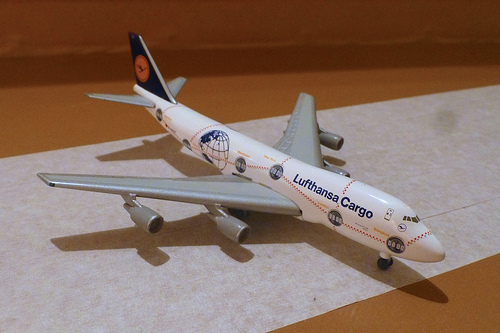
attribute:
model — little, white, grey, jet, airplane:
[24, 23, 449, 299]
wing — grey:
[13, 167, 319, 216]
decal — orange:
[126, 55, 160, 82]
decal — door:
[378, 207, 407, 222]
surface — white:
[1, 124, 498, 282]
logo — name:
[270, 165, 380, 235]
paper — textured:
[47, 253, 319, 325]